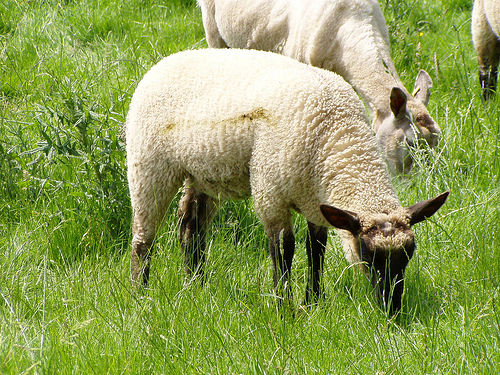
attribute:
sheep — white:
[129, 46, 450, 317]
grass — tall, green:
[1, 1, 499, 370]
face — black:
[354, 230, 417, 321]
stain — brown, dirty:
[162, 105, 272, 132]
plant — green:
[34, 72, 123, 236]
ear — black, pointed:
[319, 205, 358, 233]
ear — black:
[407, 190, 449, 226]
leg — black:
[305, 220, 328, 308]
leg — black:
[179, 193, 205, 286]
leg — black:
[269, 230, 296, 321]